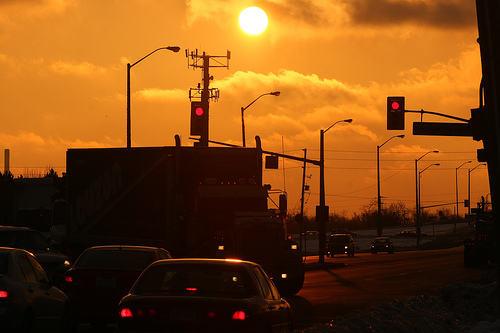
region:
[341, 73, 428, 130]
a light on a pole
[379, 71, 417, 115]
a light on a metal pole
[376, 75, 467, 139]
a traffic light on a pole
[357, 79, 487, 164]
a traffic light on a metal pole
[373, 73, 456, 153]
a pole with a light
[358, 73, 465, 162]
a metal pole with a light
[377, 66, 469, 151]
a pole with a traffic light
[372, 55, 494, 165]
a metal pole with traffic light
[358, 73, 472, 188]
a red traffic light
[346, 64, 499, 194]
red traffic light on pole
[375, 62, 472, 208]
a light on the pole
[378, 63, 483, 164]
a pole with a light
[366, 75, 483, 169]
a metal pole with a light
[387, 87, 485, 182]
a traffic light on a pole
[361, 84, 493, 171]
a traffic light on a metal pole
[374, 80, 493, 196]
a pole with a traffic light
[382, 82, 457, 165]
a red traffic light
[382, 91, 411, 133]
an overhanging traffic light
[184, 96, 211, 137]
an overhanging traffic light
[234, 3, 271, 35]
the sun in the sky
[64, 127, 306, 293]
a large truck on the road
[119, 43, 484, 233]
A row of street lights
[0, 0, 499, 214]
A clear orange sky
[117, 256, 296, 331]
a car on the road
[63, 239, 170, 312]
a car on the road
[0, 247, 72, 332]
a car on the road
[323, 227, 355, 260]
a car on the road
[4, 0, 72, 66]
part of the sky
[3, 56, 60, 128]
part of the sky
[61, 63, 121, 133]
part of the sky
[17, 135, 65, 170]
part of the sky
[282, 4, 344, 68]
part of the sky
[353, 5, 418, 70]
part of the sky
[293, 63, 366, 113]
part of the sky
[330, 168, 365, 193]
part of the sky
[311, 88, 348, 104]
part of a cloud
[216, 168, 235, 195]
part of a lorry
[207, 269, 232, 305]
part of a window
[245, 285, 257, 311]
edge of a car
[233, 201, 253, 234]
part of a truck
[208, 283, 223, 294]
part of a wondow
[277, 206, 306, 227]
part of a lorry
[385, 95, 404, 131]
a traffic light with red lit up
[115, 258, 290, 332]
a car with it's brake lights on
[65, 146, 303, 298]
a delivery truck at an intersection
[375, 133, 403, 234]
a tall street light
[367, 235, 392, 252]
a car driving with it's lights on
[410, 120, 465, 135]
a rectangular street sign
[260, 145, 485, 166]
electric power lines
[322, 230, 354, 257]
a van driving on the road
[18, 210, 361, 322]
Cars on the road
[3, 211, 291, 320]
Cars on the street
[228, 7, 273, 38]
Sun in the sky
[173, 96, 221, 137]
Traffic light above truck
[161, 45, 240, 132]
Cell phone tower above truck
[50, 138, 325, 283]
Truck on the road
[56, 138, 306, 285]
Truck on the street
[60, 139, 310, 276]
Large truck on the road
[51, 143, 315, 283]
Large truck on the street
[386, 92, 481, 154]
Traffic light on pole